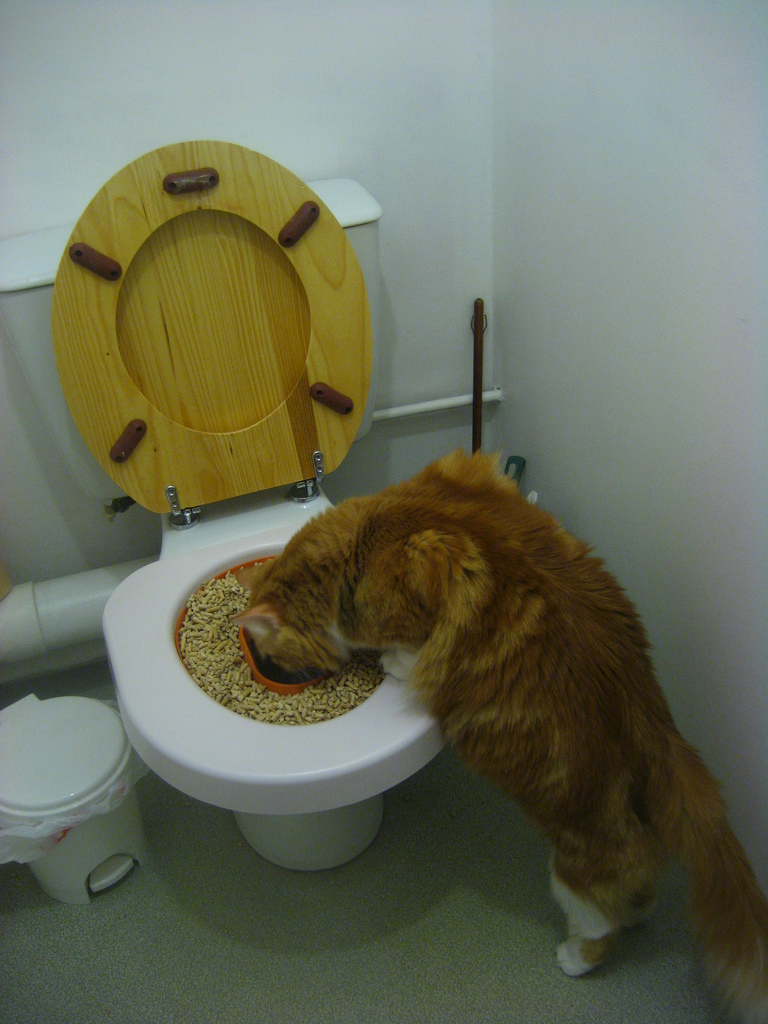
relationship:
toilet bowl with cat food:
[100, 515, 449, 816] [241, 622, 319, 682]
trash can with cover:
[0, 689, 153, 907] [2, 691, 127, 811]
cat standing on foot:
[225, 443, 765, 1022] [618, 887, 661, 929]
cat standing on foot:
[225, 443, 765, 1022] [547, 934, 613, 975]